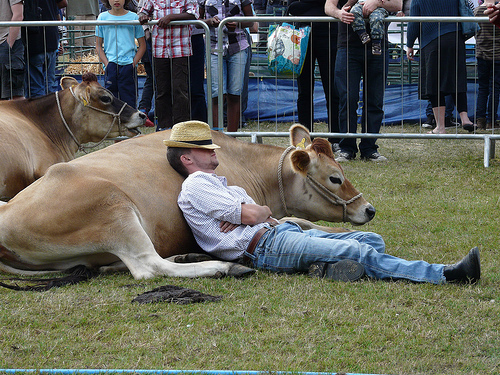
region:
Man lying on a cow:
[158, 117, 483, 290]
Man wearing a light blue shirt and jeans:
[163, 119, 483, 288]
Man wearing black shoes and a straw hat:
[165, 120, 484, 287]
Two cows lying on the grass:
[1, 69, 371, 280]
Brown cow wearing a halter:
[263, 121, 379, 238]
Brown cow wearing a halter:
[51, 68, 148, 155]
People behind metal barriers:
[0, 0, 499, 165]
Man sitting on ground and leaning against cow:
[164, 117, 482, 286]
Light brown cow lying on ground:
[0, 120, 376, 292]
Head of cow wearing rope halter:
[275, 121, 377, 228]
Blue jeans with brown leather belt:
[243, 219, 445, 286]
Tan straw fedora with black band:
[163, 118, 220, 150]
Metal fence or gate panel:
[216, 15, 498, 168]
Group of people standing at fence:
[93, 0, 405, 164]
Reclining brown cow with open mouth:
[1, 72, 148, 202]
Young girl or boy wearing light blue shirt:
[93, 0, 148, 112]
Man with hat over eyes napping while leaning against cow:
[162, 119, 482, 287]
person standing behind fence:
[2, 1, 28, 102]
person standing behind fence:
[23, 1, 67, 97]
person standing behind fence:
[94, 1, 145, 110]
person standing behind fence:
[139, 31, 154, 115]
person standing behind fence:
[137, 1, 198, 129]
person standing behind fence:
[200, 2, 259, 131]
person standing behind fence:
[288, 1, 342, 152]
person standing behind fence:
[324, 0, 400, 162]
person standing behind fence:
[405, 2, 480, 134]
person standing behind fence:
[419, 92, 463, 128]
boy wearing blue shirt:
[81, 0, 162, 134]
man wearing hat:
[148, 112, 224, 174]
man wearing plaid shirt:
[165, 155, 290, 266]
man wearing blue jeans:
[237, 196, 469, 310]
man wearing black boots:
[430, 237, 492, 297]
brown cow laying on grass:
[0, 55, 182, 208]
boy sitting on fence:
[326, 0, 414, 59]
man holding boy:
[318, 0, 408, 175]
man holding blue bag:
[261, 19, 334, 88]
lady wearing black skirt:
[401, 34, 494, 146]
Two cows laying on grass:
[0, 62, 389, 298]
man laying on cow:
[0, 100, 497, 339]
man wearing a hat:
[154, 108, 235, 168]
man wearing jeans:
[241, 189, 498, 333]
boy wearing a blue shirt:
[91, 0, 163, 138]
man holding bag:
[256, 7, 326, 99]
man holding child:
[318, 0, 429, 177]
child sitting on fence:
[323, 2, 430, 73]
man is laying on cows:
[163, 120, 481, 284]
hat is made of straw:
[163, 120, 222, 153]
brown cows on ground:
[1, 70, 375, 286]